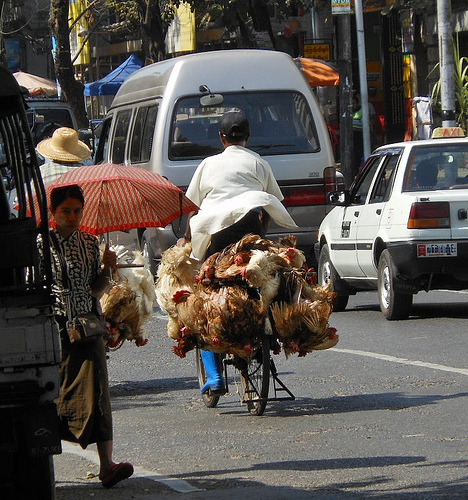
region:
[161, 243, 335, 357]
Chickens on a bike.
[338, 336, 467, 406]
White line on the road.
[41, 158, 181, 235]
Woman is holding an umbrella.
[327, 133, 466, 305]
The car is white.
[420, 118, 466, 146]
Taxi sign on the car.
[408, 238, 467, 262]
Bumper sticker on the car.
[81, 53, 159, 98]
The umbrella is blue.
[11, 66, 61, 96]
The umbrella is tan.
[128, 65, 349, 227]
The van is grey.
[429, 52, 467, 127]
Plant behind the pole.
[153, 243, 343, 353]
Chickens on a bike.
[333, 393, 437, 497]
The road is grey.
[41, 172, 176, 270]
Woman carrying an umbrella.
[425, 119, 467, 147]
Taxi sign on the car.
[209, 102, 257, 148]
The hat is black.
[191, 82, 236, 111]
Mirror on the back of the car.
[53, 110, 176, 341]
an umbrella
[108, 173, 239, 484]
an umbrella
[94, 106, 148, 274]
an umbrella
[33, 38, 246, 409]
an umbrella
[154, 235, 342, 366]
chickens hanging from the bike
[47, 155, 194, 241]
the red and white umbrella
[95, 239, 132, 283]
she holds the handle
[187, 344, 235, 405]
the blue boot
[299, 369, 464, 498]
shadows on the road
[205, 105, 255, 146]
a black trucker hat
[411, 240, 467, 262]
sticker on the bumper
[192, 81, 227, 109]
mirror on the back of the van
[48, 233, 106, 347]
a purse around his neck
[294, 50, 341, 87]
an umbrella on the sidewalk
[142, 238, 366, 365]
Dead chickens on a bicycle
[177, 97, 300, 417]
Man riding a bicycle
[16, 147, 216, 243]
An open umbrella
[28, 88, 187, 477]
Woman walking with an umbrella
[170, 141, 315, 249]
White shirt on the man on the bicycle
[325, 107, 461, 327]
White taxi on the road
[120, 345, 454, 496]
Shadows are cast to the right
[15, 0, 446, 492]
Photo taken during the day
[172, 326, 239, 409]
Blue boot on the bike peddle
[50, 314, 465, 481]
White lines on the road